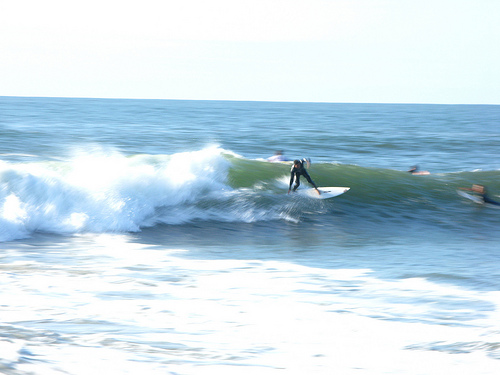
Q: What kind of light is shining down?
A: Sunlight.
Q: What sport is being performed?
A: Surfing.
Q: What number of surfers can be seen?
A: Four.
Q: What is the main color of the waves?
A: White.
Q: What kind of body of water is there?
A: An ocean.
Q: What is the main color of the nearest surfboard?
A: White.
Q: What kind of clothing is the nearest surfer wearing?
A: A wetsuit.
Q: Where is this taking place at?
A: Ocean.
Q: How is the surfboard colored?
A: White.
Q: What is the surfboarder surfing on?
A: A wave.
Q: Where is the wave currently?
A: In the middle of the ocean.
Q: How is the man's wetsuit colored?
A: Black.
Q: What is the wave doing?
A: Cresting.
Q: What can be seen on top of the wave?
A: White mist.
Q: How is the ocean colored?
A: Blue.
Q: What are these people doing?
A: Surfing.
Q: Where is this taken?
A: The beach.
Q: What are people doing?
A: Surfing.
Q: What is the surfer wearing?
A: Wetsuit.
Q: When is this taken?
A: During the day.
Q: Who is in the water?
A: People.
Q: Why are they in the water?
A: Surfing.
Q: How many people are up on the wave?
A: One.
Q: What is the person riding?
A: A surfboard.